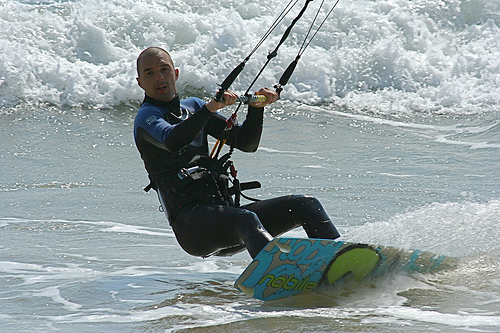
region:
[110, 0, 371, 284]
white male wind surfer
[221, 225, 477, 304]
blue gray green surf board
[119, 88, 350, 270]
black and blue wet suit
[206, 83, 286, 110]
hand grip on wind sail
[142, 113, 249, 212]
safety harness on man's waist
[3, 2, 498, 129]
sea foam in distance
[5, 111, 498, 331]
calm water near surfer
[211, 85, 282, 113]
two hands gripping handle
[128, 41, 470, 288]
surfer tipping backwards on board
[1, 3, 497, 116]
large wave crashing in background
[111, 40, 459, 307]
a man on a surfboard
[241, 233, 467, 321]
a blue and green surfboard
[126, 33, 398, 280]
a man in a wetsuit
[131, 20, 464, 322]
a man having fun in the water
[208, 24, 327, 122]
a man holding on to a pole with wires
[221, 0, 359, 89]
wires attached to a pole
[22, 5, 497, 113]
white foamy water behind man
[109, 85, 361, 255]
a blue and black wetsuit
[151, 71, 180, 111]
goatee on man's face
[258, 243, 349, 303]
blue writing on bottom of board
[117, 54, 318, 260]
young man para surfing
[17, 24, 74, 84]
short green and brown grass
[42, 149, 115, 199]
short green and brown grass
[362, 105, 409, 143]
short green and brown grass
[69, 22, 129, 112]
short green and brown grass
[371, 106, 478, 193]
short green and brown grass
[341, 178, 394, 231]
short green and brown grass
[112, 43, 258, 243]
person para surfing in ocean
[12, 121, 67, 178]
white and gray ocean waves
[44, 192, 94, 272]
white and gray ocean waves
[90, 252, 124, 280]
white and gray ocean waves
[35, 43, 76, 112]
white and gray ocean waves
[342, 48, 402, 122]
white and gray ocean waves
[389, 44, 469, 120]
white and gray ocean waves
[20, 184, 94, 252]
white and gray ocean waves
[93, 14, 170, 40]
white and gray ocean waves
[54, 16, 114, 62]
a wave at the sea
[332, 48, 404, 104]
a wave at the sea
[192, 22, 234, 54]
a wave at the sea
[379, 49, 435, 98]
a wave at the sea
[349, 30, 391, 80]
a wave at the sea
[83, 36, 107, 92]
a wave at the sea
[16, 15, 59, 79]
a wave at the sea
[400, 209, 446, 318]
a wave at the sea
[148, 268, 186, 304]
a wave at the sea